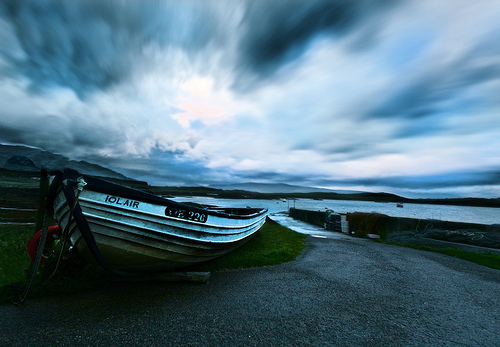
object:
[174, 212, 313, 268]
grass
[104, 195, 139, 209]
name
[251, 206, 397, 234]
dock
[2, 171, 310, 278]
grass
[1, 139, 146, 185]
mountain range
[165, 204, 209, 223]
number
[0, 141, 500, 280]
hills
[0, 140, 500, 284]
boat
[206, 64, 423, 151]
ground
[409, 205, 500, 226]
blue shirt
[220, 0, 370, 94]
cloud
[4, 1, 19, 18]
cloud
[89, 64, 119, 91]
cloud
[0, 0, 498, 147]
sky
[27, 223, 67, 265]
light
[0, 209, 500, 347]
path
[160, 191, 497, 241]
water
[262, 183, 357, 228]
lack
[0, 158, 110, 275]
car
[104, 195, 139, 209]
letters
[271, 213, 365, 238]
ramp